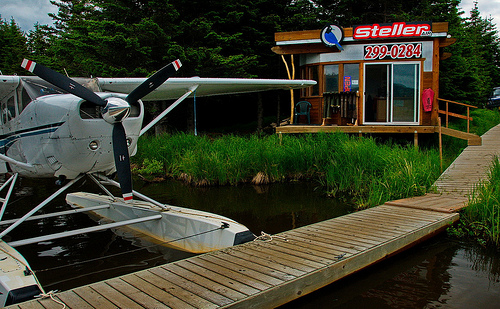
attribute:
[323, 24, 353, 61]
bird — blue, black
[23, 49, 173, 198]
propellers — black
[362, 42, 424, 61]
number — glass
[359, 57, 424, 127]
door — sliding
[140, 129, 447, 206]
grass — tall, lush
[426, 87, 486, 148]
fence — wooden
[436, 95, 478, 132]
hand rail — wooden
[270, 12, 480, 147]
building — wood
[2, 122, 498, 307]
boardwalk — wooden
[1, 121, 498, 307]
dock — wooden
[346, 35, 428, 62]
numbers — red, black, white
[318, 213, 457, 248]
walkway — wooden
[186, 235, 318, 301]
bridge — narrow, wooden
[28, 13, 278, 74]
leaves — green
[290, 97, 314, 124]
chair — plastic, green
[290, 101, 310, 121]
chair — green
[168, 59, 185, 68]
stripes — white, red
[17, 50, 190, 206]
propeller — black